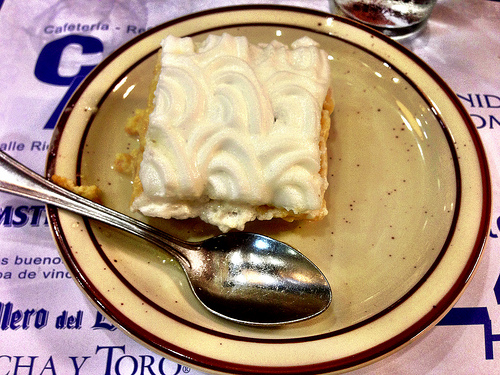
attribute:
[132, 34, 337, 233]
pie — delicious, square, lemon marange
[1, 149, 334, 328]
spoon — clean, silver, metal, "stainless steel, tarnished, old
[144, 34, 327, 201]
frosting — white, wavy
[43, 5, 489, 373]
plate — tan, brown, speckled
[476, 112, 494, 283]
rim — brown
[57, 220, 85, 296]
rim — brown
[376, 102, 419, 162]
specks — dark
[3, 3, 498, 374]
mat — purple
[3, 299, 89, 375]
writing — blue, spanish